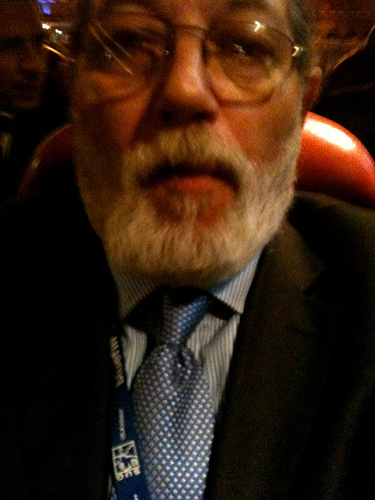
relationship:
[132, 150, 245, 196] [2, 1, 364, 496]
mouth of a man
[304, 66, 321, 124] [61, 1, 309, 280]
ear of a man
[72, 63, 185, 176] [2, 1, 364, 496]
cheek of a man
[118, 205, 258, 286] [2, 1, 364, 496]
chin of a man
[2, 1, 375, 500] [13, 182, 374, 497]
man wearing a shirt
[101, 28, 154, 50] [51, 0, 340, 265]
eye belonging to man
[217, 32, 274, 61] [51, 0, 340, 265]
eye belonging to man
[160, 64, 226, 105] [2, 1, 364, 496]
nose belonging to man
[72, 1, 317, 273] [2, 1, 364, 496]
face belonging to man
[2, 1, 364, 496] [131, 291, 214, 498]
man wearing tie